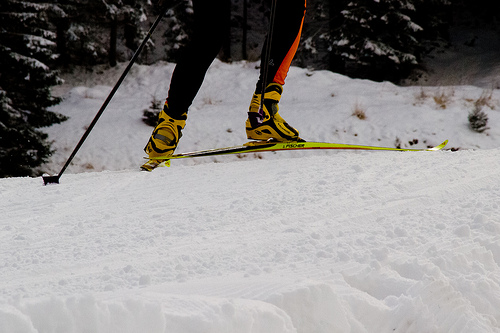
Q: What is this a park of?
A: A hokker.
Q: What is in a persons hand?
A: A ski pole.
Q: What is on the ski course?
A: Snow.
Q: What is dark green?
A: The pine tree.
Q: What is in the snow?
A: A skier's legs.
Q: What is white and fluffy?
A: Snow on the ground.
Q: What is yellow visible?
A: A pair of skis.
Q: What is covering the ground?
A: Snow.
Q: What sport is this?
A: Skiing.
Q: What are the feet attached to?
A: The skiis.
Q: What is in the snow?
A: Prints.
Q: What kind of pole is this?
A: A ski pole.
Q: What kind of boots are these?
A: Ski boots.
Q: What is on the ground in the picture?
A: Snow.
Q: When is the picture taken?
A: Daytime.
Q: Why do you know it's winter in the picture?
A: The snow.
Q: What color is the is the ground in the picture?
A: White.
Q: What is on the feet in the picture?
A: Ski's.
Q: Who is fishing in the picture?
A: No one.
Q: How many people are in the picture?
A: One.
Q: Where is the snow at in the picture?
A: Everywhere.